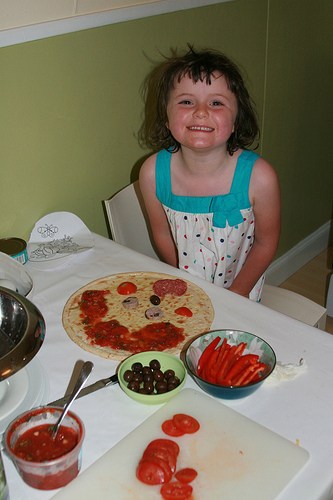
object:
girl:
[138, 41, 281, 299]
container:
[3, 406, 86, 491]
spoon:
[51, 361, 93, 440]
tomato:
[172, 413, 199, 434]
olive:
[150, 359, 160, 370]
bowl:
[116, 351, 186, 406]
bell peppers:
[195, 335, 221, 377]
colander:
[0, 285, 47, 383]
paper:
[25, 209, 95, 271]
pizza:
[62, 272, 213, 360]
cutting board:
[47, 389, 311, 500]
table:
[0, 230, 333, 500]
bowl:
[184, 329, 276, 400]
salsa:
[14, 423, 83, 490]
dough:
[62, 271, 214, 361]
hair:
[148, 41, 262, 156]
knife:
[45, 373, 119, 408]